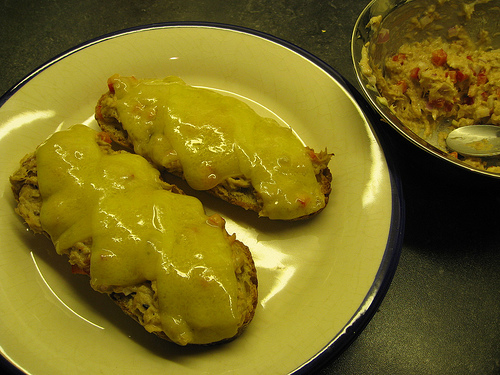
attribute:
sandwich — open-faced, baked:
[102, 73, 345, 216]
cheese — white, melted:
[130, 85, 313, 201]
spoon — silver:
[450, 113, 499, 159]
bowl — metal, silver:
[353, 3, 500, 177]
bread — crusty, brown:
[100, 78, 332, 218]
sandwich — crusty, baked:
[15, 126, 259, 344]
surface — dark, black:
[5, 4, 488, 372]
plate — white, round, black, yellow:
[4, 23, 398, 374]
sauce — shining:
[40, 76, 326, 311]